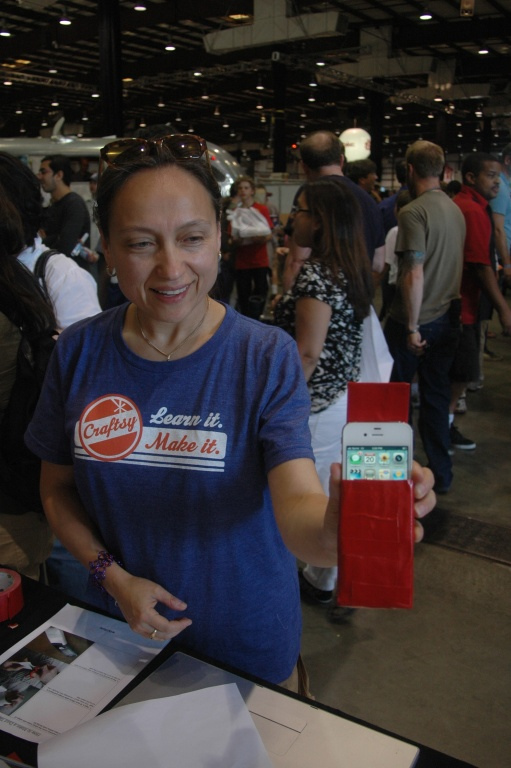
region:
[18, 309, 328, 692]
the shirt is blue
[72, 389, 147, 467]
the logo is round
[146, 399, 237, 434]
white letters on a shirt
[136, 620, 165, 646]
a ring on a finger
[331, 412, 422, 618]
the phone is in a red bag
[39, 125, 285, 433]
woman wears a necklace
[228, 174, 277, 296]
man wears a red shirt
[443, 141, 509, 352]
man has red shirt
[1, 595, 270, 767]
the paper is white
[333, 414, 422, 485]
White cell phone in a case.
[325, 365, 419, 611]
Red case holding a cell phone.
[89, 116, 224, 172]
Sunglasses worn upon the head.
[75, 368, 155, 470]
Red words on front of a shirt.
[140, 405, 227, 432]
White words on a blue shirt.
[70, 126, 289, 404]
Woman wearing a blue shirt.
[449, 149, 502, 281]
Man wearing a red shirt.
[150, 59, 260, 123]
Lights in the ceiling.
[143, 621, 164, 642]
Gold ring on a finger.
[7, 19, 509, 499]
an exhibition or show is in progress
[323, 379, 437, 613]
a cell phone in a pocket is displayed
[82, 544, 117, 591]
a lady is wearing a bracelet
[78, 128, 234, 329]
sunglasses are on the lady's head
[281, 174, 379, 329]
the girl has long brown hair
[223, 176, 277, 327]
the lady is carrying a full plastic bag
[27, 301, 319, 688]
She is wearing a blue t-shirt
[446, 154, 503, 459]
the man is wearing black and white sneakers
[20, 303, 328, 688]
the shirt is color blue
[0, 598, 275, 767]
paper on a table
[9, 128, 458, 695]
woman holding a red cell phone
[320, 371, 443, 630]
hand holding a cell phone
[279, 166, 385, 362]
woman is black hair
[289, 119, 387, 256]
the man is bald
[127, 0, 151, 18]
light is on the ceiling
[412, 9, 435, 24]
light is on the ceiling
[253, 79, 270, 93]
light is on the ceiling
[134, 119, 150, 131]
light is on the ceiling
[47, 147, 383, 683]
A person is standing up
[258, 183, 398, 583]
A person is standing up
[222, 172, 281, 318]
A person is standing up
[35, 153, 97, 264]
A person is standing up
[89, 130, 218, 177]
brown plastic sunglasses on head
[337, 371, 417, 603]
red phone case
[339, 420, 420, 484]
white iphone in case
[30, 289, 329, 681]
short sleeve blue shirt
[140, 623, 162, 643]
gold ring on finger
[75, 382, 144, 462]
orange circle on front of shirt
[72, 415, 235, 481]
white stripes on blue shirt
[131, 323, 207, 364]
gold necklace on neck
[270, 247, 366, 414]
black floral shirt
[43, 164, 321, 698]
A person is standing up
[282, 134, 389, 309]
A person is standing up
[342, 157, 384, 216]
A person is standing up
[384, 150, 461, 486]
A person is standing up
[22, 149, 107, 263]
A person is standing up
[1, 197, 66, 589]
A person is standing up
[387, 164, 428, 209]
A person is standing up